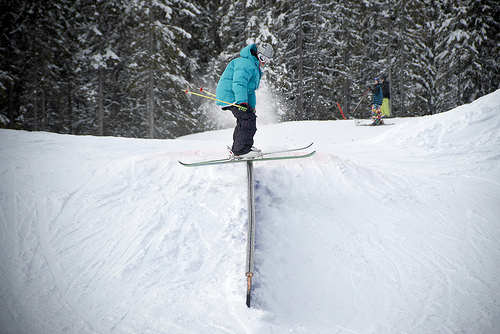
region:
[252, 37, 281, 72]
the head of a person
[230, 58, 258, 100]
the arm of a person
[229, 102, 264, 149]
the legs of a person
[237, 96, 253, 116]
the hand of a person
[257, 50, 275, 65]
a pair of goggles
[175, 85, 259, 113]
a yellow and red ski pole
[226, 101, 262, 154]
a pair of black pants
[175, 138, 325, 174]
a pair of skis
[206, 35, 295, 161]
a person skiing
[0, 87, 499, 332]
white snow on the ground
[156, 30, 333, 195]
boy skiing on a rail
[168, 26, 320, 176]
boy doing ski tricks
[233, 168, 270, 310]
metal railing for skiing tricks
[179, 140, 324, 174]
pair of skis sideways on a rail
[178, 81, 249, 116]
yellow and hot pink ski poles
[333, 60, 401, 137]
two skiing spectators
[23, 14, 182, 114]
snow covered pine trees on top of a mountain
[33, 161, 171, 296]
ski tracks on the snow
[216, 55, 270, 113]
light blue ski parka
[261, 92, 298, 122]
snow spray from the skier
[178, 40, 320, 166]
A man skiiting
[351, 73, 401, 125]
Two people on skis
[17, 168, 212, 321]
Marks in the white snow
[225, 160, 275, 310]
A thin metal ledge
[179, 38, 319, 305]
A man skiing on a metal ledge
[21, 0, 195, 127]
Snowy pine trees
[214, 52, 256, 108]
A bright blue jacket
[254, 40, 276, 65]
A gray helmet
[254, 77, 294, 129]
A cloud of snow thrown into the air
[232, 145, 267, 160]
A pair of white shoes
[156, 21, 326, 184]
Person is skiing down a small hill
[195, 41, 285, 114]
Person is wearing a light blue coat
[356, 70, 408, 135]
People are in the background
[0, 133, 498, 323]
Ground is covered in snow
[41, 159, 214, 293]
Tracks are in the snow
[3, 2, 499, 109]
Trees are in the background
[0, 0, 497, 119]
Trees are snow covered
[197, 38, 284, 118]
Person is wearing a bubble jacket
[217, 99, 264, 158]
Person is wearing dark pants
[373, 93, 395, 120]
Person in the background is wearing yellow pants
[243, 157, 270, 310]
A ski rail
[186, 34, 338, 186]
a skier on the rail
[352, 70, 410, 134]
a pair of skiers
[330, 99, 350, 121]
an orange pole sticking out of the ground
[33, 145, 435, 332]
ski marks in the snow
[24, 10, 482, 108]
snow covered trees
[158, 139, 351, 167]
orange paint on the snow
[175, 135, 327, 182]
a pair of skis on the skier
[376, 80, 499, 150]
a snowy hill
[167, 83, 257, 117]
Yellow and orange ski poles